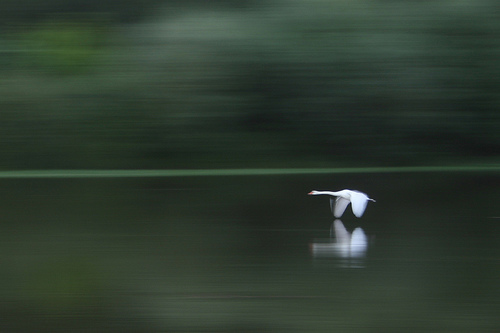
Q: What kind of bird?
A: Crane.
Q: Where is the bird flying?
A: Wings.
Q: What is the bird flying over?
A: Water.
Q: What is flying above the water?
A: Bird.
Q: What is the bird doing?
A: Flying.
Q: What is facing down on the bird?
A: Wings.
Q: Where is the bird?
A: Above water.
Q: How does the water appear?
A: Calm.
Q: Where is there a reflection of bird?
A: In water.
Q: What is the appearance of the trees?
A: Blurry.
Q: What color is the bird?
A: White.